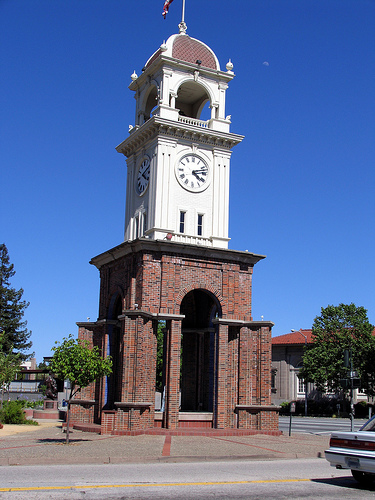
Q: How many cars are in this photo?
A: One.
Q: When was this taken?
A: Daytime.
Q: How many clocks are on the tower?
A: One.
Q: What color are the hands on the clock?
A: Black.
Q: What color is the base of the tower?
A: Brown.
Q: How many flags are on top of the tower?
A: One.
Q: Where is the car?
A: In the street.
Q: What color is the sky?
A: Blue.